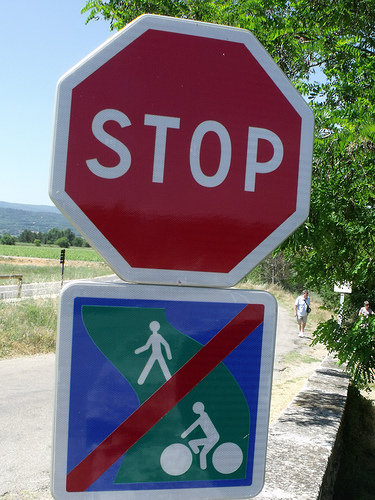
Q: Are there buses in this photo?
A: No, there are no buses.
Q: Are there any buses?
A: No, there are no buses.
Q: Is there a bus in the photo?
A: No, there are no buses.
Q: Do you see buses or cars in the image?
A: No, there are no buses or cars.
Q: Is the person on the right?
A: Yes, the person is on the right of the image.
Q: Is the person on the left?
A: No, the person is on the right of the image.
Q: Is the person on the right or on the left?
A: The person is on the right of the image.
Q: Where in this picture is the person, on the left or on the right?
A: The person is on the right of the image.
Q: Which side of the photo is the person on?
A: The person is on the right of the image.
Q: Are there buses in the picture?
A: No, there are no buses.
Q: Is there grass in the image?
A: Yes, there is grass.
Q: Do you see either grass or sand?
A: Yes, there is grass.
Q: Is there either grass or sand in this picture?
A: Yes, there is grass.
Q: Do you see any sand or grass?
A: Yes, there is grass.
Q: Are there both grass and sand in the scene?
A: No, there is grass but no sand.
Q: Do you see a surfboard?
A: No, there are no surfboards.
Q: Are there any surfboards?
A: No, there are no surfboards.